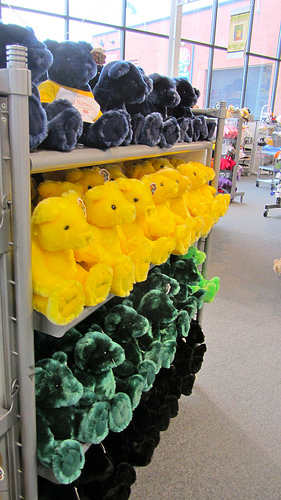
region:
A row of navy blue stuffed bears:
[5, 17, 210, 141]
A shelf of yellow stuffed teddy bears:
[34, 151, 221, 310]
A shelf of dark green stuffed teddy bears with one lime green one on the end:
[34, 245, 205, 479]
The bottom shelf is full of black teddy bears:
[31, 316, 209, 497]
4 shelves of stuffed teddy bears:
[1, 20, 220, 494]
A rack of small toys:
[211, 107, 253, 205]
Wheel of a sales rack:
[258, 201, 278, 216]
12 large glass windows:
[0, 2, 277, 111]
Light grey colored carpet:
[189, 301, 274, 494]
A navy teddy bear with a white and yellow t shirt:
[47, 38, 108, 148]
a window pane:
[246, 69, 251, 81]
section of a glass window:
[212, 47, 222, 65]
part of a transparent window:
[198, 15, 205, 23]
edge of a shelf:
[164, 144, 180, 155]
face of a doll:
[96, 339, 118, 365]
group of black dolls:
[108, 340, 197, 469]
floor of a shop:
[245, 227, 260, 250]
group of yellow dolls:
[138, 182, 199, 237]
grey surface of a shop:
[196, 439, 214, 469]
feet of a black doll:
[82, 412, 104, 451]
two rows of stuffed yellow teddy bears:
[36, 164, 229, 325]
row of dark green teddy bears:
[33, 258, 206, 482]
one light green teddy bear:
[180, 245, 220, 303]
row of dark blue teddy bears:
[1, 17, 215, 146]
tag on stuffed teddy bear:
[147, 183, 159, 196]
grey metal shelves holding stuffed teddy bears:
[1, 43, 227, 498]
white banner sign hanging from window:
[227, 6, 253, 61]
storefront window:
[74, 3, 210, 55]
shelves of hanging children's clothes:
[220, 103, 252, 204]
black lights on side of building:
[92, 33, 118, 47]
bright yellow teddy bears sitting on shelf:
[32, 169, 227, 281]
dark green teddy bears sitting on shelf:
[38, 312, 243, 463]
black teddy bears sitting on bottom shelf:
[45, 402, 245, 499]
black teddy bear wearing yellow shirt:
[36, 36, 113, 149]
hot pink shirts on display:
[216, 152, 242, 174]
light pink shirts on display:
[219, 115, 245, 147]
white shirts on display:
[221, 137, 237, 158]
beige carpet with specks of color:
[219, 260, 278, 438]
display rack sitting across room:
[253, 98, 280, 190]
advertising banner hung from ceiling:
[224, 5, 253, 73]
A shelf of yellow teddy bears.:
[23, 132, 241, 317]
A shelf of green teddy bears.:
[25, 240, 225, 481]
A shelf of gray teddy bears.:
[2, 16, 221, 147]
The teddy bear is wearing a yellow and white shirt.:
[31, 28, 127, 151]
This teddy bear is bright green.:
[183, 244, 221, 302]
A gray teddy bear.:
[147, 68, 189, 146]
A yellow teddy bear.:
[31, 195, 98, 324]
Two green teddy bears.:
[30, 323, 133, 484]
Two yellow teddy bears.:
[24, 178, 143, 313]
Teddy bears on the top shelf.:
[0, 15, 232, 152]